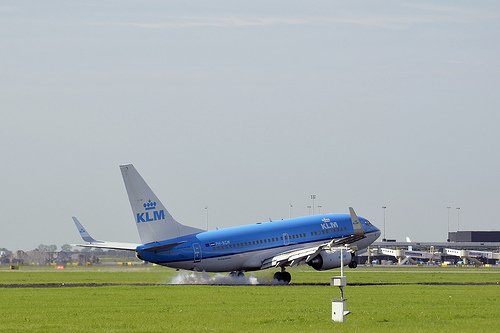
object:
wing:
[56, 213, 148, 259]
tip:
[62, 211, 89, 236]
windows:
[207, 245, 225, 253]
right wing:
[232, 201, 375, 274]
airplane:
[54, 151, 394, 312]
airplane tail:
[114, 152, 214, 250]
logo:
[128, 195, 171, 228]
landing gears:
[219, 260, 304, 288]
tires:
[266, 269, 297, 288]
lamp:
[399, 232, 417, 263]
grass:
[0, 291, 67, 330]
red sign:
[52, 263, 67, 273]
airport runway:
[0, 250, 498, 325]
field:
[1, 293, 494, 331]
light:
[326, 242, 354, 324]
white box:
[322, 242, 355, 326]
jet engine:
[297, 239, 371, 277]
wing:
[239, 203, 376, 273]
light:
[453, 205, 464, 212]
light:
[443, 204, 453, 211]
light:
[379, 204, 389, 211]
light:
[306, 191, 321, 202]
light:
[315, 203, 326, 209]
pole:
[454, 209, 463, 235]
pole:
[379, 207, 389, 244]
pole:
[309, 197, 317, 220]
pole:
[316, 207, 323, 215]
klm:
[128, 193, 174, 230]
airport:
[0, 222, 498, 331]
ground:
[400, 296, 491, 331]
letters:
[129, 196, 171, 229]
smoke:
[159, 265, 291, 292]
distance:
[0, 224, 497, 273]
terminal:
[351, 229, 497, 274]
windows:
[231, 240, 248, 250]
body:
[124, 206, 396, 284]